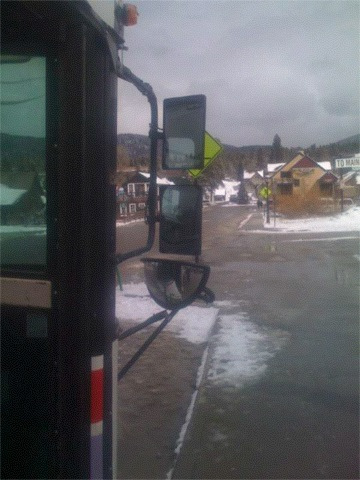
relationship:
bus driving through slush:
[0, 0, 216, 479] [116, 280, 276, 390]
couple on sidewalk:
[254, 197, 264, 209] [238, 201, 266, 232]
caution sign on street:
[257, 183, 274, 223] [100, 196, 356, 477]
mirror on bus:
[162, 93, 207, 170] [2, 1, 206, 479]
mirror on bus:
[159, 183, 202, 250] [2, 1, 206, 479]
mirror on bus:
[143, 259, 208, 308] [2, 1, 206, 479]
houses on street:
[241, 117, 350, 228] [0, 200, 355, 476]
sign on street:
[186, 129, 222, 178] [226, 245, 344, 399]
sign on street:
[260, 186, 272, 198] [226, 245, 344, 399]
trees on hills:
[253, 131, 285, 165] [219, 124, 359, 156]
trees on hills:
[306, 140, 332, 158] [219, 124, 359, 156]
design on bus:
[80, 332, 128, 479] [2, 1, 206, 479]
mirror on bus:
[159, 184, 203, 256] [2, 1, 206, 479]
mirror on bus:
[162, 93, 207, 170] [19, 8, 204, 387]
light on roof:
[121, 3, 140, 25] [50, 0, 130, 68]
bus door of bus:
[0, 0, 91, 480] [2, 1, 206, 479]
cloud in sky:
[232, 74, 312, 125] [154, 19, 356, 89]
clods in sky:
[209, 17, 286, 80] [89, 1, 356, 150]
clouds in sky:
[236, 54, 321, 128] [89, 1, 356, 150]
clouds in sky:
[183, 22, 357, 148] [200, 29, 314, 98]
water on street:
[251, 266, 336, 317] [221, 212, 325, 400]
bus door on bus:
[0, 0, 91, 480] [3, 5, 179, 475]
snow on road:
[169, 297, 277, 399] [114, 202, 358, 478]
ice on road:
[151, 339, 190, 382] [114, 202, 358, 478]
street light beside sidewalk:
[263, 179, 272, 225] [257, 211, 358, 231]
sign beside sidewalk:
[250, 180, 277, 203] [257, 211, 358, 231]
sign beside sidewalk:
[179, 125, 227, 182] [257, 211, 358, 231]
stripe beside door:
[84, 352, 117, 473] [11, 4, 122, 479]